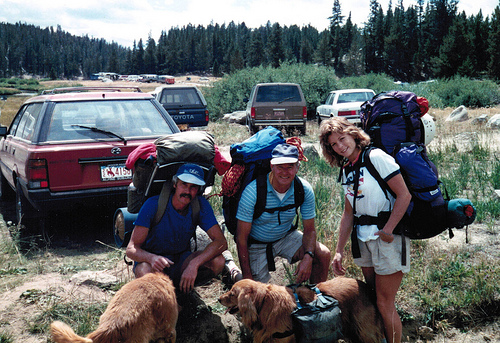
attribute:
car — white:
[311, 85, 379, 125]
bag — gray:
[277, 282, 349, 334]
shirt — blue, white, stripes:
[247, 174, 309, 229]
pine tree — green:
[143, 31, 159, 73]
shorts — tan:
[353, 234, 411, 276]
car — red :
[0, 91, 183, 253]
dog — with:
[211, 268, 381, 342]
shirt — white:
[337, 150, 412, 232]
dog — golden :
[48, 274, 182, 341]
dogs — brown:
[49, 272, 381, 342]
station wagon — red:
[0, 92, 185, 252]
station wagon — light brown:
[240, 80, 310, 150]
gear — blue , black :
[356, 87, 475, 237]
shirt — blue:
[119, 172, 236, 270]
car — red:
[0, 90, 187, 231]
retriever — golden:
[49, 267, 183, 342]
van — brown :
[242, 67, 317, 139]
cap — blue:
[174, 162, 209, 187]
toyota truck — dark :
[241, 82, 296, 127]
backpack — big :
[359, 91, 475, 239]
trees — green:
[289, 14, 429, 94]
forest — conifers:
[2, 1, 497, 81]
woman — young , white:
[315, 116, 427, 340]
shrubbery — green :
[213, 70, 496, 122]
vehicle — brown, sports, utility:
[236, 69, 326, 140]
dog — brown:
[85, 261, 206, 329]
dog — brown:
[219, 268, 393, 335]